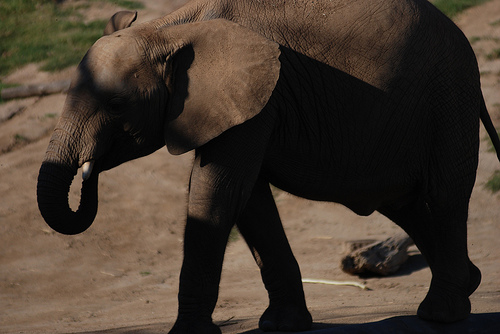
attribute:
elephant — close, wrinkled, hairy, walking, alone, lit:
[36, 1, 498, 334]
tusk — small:
[81, 159, 92, 181]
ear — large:
[163, 17, 281, 155]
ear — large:
[106, 10, 138, 32]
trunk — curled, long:
[36, 125, 99, 234]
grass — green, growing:
[0, 0, 498, 199]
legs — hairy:
[166, 103, 313, 333]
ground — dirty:
[1, 2, 499, 334]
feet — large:
[167, 257, 480, 333]